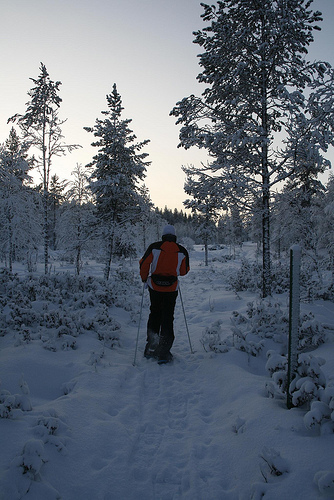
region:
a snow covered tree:
[81, 81, 155, 284]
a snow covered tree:
[32, 59, 54, 275]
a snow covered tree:
[186, 0, 306, 298]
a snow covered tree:
[0, 121, 26, 292]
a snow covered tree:
[67, 161, 90, 281]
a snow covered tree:
[198, 189, 218, 265]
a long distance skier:
[141, 215, 193, 366]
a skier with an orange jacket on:
[137, 223, 196, 303]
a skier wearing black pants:
[139, 221, 187, 368]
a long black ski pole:
[178, 285, 208, 357]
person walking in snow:
[133, 223, 197, 364]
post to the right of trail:
[286, 244, 298, 407]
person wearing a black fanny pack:
[149, 271, 176, 286]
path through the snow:
[93, 256, 207, 498]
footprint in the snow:
[201, 407, 211, 423]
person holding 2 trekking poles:
[179, 278, 199, 353]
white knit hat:
[162, 224, 175, 236]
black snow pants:
[145, 288, 177, 335]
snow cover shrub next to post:
[266, 348, 326, 406]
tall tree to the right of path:
[168, 0, 333, 296]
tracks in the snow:
[100, 344, 237, 494]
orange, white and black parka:
[137, 238, 193, 291]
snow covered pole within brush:
[275, 235, 317, 408]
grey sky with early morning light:
[3, 1, 330, 215]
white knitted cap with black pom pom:
[162, 213, 179, 233]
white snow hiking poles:
[131, 270, 193, 365]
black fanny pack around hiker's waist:
[146, 271, 185, 288]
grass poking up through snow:
[252, 444, 296, 493]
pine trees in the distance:
[148, 201, 215, 228]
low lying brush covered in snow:
[2, 260, 144, 367]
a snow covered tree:
[49, 173, 61, 256]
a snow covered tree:
[184, 166, 221, 269]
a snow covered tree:
[287, 135, 333, 283]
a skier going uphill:
[130, 216, 206, 365]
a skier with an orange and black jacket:
[137, 229, 195, 300]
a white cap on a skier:
[156, 223, 178, 241]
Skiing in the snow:
[119, 218, 208, 375]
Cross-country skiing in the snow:
[119, 210, 214, 374]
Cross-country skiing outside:
[124, 220, 207, 373]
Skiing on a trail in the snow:
[6, 98, 328, 494]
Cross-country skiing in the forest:
[7, 65, 332, 492]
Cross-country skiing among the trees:
[6, 14, 327, 495]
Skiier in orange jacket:
[126, 219, 202, 370]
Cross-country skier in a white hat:
[120, 220, 205, 380]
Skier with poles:
[125, 212, 204, 374]